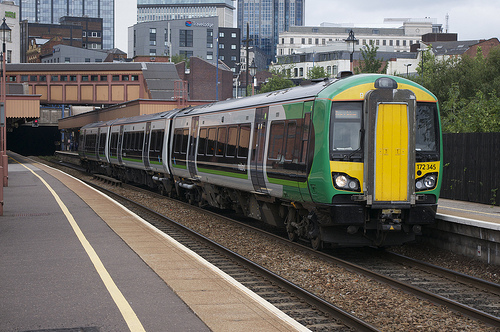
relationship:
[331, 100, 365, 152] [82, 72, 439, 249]
window on train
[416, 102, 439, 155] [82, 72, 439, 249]
window on train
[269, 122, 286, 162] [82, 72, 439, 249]
window on train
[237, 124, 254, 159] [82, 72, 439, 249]
window on train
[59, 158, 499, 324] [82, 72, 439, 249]
track under train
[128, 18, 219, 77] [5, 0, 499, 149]
building in background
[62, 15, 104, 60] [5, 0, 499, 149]
building in background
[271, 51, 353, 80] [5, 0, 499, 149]
building in background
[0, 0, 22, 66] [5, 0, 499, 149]
building in background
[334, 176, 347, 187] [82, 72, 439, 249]
light on train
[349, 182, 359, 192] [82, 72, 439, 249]
light on train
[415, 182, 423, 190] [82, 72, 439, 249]
light on train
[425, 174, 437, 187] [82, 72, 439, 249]
light on train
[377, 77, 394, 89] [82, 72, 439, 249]
light on train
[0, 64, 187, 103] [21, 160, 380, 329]
bridge over tracks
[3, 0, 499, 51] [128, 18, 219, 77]
sky behind building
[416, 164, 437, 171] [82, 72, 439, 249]
number on train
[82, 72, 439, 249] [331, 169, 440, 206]
train look like face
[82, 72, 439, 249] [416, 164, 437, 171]
train has 172345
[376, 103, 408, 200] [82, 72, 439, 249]
door on train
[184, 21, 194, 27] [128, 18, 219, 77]
logo on building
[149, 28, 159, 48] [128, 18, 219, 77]
window on building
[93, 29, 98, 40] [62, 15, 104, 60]
window on building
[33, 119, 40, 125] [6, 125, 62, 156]
stoplight in tunnel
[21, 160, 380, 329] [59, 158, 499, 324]
gravel beside track